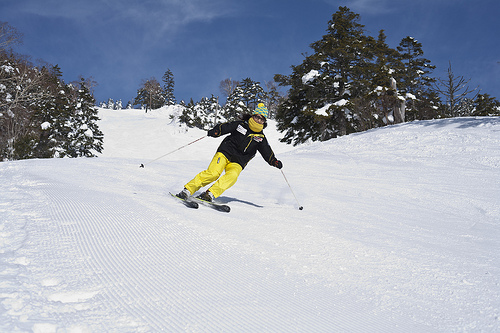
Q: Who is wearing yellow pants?
A: Skier.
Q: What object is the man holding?
A: Ski pole.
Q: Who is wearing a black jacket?
A: Skier.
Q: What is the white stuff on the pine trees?
A: Snow.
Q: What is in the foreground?
A: Snow.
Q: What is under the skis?
A: Snow.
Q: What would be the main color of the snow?
A: White.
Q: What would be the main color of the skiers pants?
A: Yellow.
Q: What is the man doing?
A: Skiing.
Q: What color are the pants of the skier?
A: Yellow.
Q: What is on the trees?
A: Snow.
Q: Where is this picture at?
A: A mountain.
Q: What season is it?
A: Winter.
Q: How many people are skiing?
A: One.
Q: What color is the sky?
A: Blue.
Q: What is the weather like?
A: Sunny.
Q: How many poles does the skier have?
A: Two.